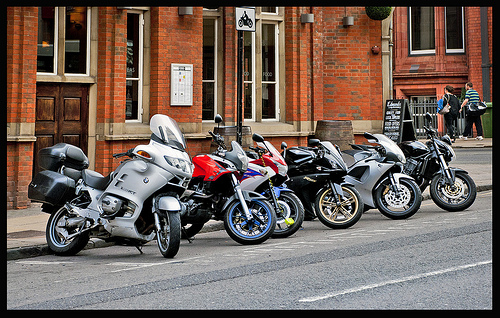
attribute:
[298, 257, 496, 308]
line — white